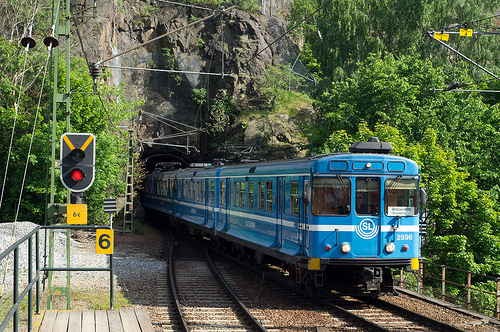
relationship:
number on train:
[395, 232, 413, 240] [140, 133, 424, 299]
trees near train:
[293, 58, 498, 268] [131, 156, 419, 266]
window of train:
[263, 178, 273, 213] [208, 124, 449, 306]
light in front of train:
[340, 241, 350, 254] [140, 133, 424, 299]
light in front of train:
[385, 243, 395, 253] [140, 133, 424, 299]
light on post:
[72, 169, 82, 179] [62, 0, 74, 310]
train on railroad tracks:
[140, 135, 428, 294] [213, 246, 465, 331]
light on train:
[340, 241, 350, 254] [140, 135, 428, 294]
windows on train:
[137, 168, 304, 220] [140, 135, 428, 294]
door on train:
[271, 172, 287, 247] [140, 135, 428, 294]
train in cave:
[226, 144, 416, 293] [114, 67, 306, 262]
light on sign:
[72, 169, 82, 179] [59, 131, 96, 191]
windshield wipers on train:
[326, 163, 413, 209] [111, 114, 451, 291]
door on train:
[280, 175, 303, 243] [140, 135, 428, 294]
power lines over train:
[97, 1, 235, 153] [140, 135, 428, 294]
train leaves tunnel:
[140, 135, 428, 294] [127, 152, 192, 225]